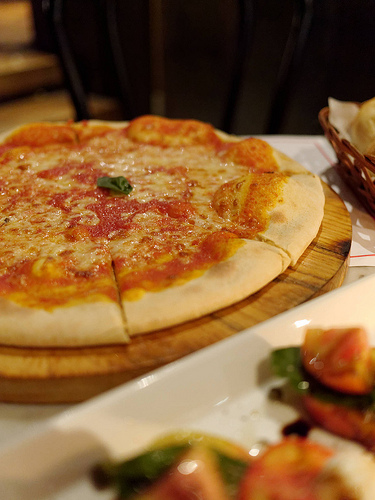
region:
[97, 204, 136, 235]
sauce on the pizza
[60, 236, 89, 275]
cheese on the pizza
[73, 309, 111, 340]
crust on the pizza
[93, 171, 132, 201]
lettuce on the pizza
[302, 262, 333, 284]
wooden tray on the table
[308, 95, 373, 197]
basket on the table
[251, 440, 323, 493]
tomatoes on the plate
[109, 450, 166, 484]
lettuce on the tray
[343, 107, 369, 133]
napkin in the basket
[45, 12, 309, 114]
chair in back of the table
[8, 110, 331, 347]
a pizza with cheese on top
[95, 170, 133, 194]
small sprig of green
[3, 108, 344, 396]
pizza on a round cutting board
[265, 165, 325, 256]
lightly baked crust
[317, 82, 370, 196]
food in a small basket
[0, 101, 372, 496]
varied food on a table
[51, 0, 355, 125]
black rungs of a chair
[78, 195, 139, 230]
red sauce on the piza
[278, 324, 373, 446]
shiny food on a white platter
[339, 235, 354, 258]
black circle on the wood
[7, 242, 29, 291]
part of the cheese pizza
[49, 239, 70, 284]
part of the cheese pizza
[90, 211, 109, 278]
part of the cheese pizza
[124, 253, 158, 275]
part of the cheese pizza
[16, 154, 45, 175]
part of the cheese pizza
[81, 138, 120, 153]
part of the cheese pizza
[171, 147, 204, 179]
part of the cheese pizza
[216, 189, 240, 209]
part of the cheese pizza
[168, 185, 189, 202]
part of the cheese pizza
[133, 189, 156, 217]
part of the cheese pizza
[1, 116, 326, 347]
sliced pizza on plate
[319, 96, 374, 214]
rolls in wicker basket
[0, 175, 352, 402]
round cutting board under pizza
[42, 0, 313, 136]
black backrest on chair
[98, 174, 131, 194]
green vegetable on pizza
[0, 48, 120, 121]
wooden stairs behind chair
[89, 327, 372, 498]
sliced appetizers on plate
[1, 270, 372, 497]
square plate under appetizers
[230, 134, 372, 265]
white and red napkin under basket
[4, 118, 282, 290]
large air pockets on pizza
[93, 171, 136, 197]
A piece of basil centered on a pizza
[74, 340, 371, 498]
Tomatoes and bail resting on a white tray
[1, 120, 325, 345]
A plain pizza with basil on top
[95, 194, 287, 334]
a slice of pizza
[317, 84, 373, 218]
A basket of bread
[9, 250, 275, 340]
the crust of a pizza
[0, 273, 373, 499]
a white serving tray with tomatoes on it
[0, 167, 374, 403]
Wooden cutting board with pizza on top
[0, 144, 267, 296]
Tomato and cheese pizza toppings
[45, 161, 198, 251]
Red tomato based pizza sauce